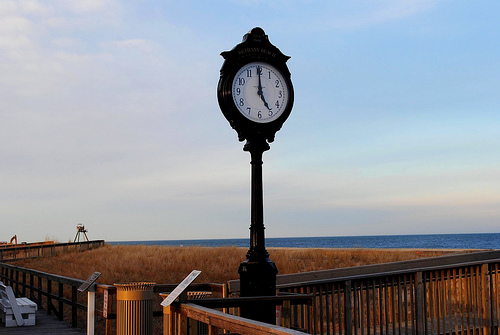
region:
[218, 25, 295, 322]
Clock reads 5 o'clock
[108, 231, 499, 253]
the water is blue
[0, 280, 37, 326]
folding chair is white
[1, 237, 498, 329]
fence is made of wood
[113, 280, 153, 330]
trashcan is brown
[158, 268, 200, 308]
this white sign is larger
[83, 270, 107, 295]
smaller sign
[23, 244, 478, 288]
the growth on the beach is yellow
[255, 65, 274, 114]
two hands on the clock face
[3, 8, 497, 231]
partially cloudy sky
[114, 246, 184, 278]
ground covered in brown grass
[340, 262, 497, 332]
grey metal guard railing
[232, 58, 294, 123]
large white clock face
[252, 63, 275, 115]
black metal clock face hands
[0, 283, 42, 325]
wooden white bench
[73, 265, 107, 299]
metal plaque on boardwalk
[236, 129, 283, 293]
black metal clock pole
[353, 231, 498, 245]
calm surface of water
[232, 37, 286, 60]
white writing above clock face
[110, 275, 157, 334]
beige metal trashcan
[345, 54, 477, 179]
a clear blue sky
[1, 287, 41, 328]
white wooden bench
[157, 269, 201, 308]
a plaque on the railing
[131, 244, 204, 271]
tall brown sea grass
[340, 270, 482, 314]
wooden railing on the pier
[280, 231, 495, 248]
smooth placid blue ocean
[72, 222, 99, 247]
a tall contarption on the beach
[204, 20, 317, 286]
a tall black clock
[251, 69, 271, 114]
black hands on a white clock face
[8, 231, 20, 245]
the top of a crane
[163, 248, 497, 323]
walkway to the water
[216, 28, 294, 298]
tall, fancy clock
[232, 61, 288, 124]
clock face is white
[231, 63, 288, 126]
black numbers on the clock face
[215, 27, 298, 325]
clock is behind the railing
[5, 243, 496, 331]
the grass looks very dry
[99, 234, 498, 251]
dark blue open water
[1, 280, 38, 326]
seating behind the fence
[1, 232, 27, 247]
yellow equiptment in the distance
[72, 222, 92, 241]
a tall tower near the waters edge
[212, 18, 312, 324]
clock and black stand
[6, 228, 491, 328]
railings along boardwalk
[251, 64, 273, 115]
hands on the clock face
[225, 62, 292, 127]
numbers on the clock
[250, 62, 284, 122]
clock hands showing 5 o'clock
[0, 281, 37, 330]
white bench on boardwalk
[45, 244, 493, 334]
dried grass in front of boardwalk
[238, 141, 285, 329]
stand clock is on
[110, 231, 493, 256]
ocean on the horizon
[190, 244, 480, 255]
small strip of sand